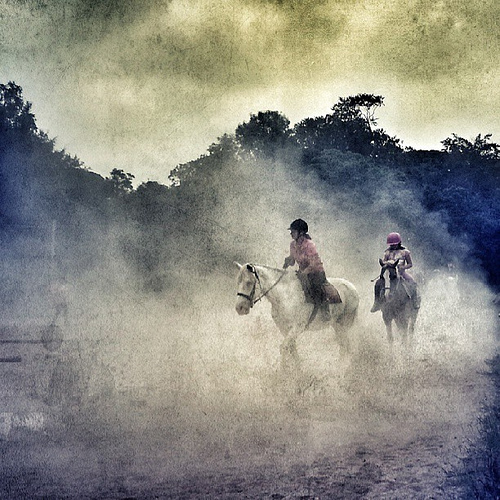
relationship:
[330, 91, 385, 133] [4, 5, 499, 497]
tree in forest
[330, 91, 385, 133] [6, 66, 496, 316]
tree in forest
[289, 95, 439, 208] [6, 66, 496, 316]
tree in forest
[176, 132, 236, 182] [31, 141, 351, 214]
tree top in forest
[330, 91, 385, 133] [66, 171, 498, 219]
tree in forest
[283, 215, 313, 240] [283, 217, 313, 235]
head wearing helmet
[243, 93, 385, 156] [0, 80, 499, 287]
leaves on trees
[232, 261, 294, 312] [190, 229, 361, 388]
bridle on horse